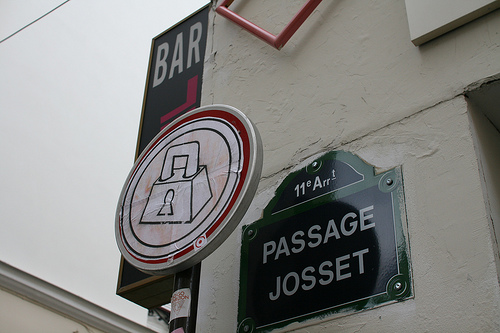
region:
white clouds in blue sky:
[47, 33, 81, 58]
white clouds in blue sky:
[75, 100, 103, 122]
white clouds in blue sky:
[19, 142, 68, 175]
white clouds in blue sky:
[4, 219, 40, 241]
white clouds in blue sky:
[5, 195, 41, 227]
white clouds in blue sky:
[16, 98, 64, 145]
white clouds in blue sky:
[39, 221, 96, 258]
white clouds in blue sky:
[58, 142, 95, 163]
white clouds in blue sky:
[49, 45, 83, 71]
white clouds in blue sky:
[7, 37, 31, 71]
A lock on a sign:
[136, 139, 213, 224]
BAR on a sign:
[149, 18, 209, 87]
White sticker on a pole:
[167, 290, 192, 319]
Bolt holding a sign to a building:
[393, 280, 400, 289]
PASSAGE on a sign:
[257, 201, 387, 265]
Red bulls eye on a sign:
[192, 233, 211, 248]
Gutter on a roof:
[0, 258, 171, 331]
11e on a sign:
[289, 180, 314, 196]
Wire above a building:
[0, 0, 81, 51]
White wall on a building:
[194, 3, 494, 331]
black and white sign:
[267, 143, 412, 298]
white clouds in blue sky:
[35, 21, 109, 79]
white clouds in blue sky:
[48, 18, 89, 55]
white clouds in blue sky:
[35, 83, 76, 128]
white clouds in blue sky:
[25, 146, 59, 188]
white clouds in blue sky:
[18, 205, 55, 250]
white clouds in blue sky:
[62, 156, 90, 183]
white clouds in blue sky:
[7, 99, 45, 134]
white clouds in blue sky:
[47, 59, 109, 104]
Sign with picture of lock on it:
[115, 100, 265, 275]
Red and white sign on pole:
[105, 100, 262, 270]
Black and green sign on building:
[235, 150, 427, 330]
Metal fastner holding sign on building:
[391, 280, 401, 290]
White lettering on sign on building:
[255, 202, 375, 297]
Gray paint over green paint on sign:
[268, 300, 410, 332]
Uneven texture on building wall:
[226, 34, 451, 166]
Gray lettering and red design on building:
[149, 18, 209, 130]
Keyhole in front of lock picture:
[155, 189, 179, 217]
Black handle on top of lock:
[158, 141, 201, 179]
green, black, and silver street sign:
[231, 143, 415, 326]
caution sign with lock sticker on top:
[115, 98, 262, 332]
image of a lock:
[134, 135, 216, 228]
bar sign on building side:
[113, 0, 209, 316]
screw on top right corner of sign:
[382, 176, 395, 187]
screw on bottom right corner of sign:
[393, 280, 400, 287]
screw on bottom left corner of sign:
[238, 320, 249, 330]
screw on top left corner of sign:
[245, 226, 252, 233]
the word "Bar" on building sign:
[147, 20, 204, 90]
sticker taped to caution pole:
[166, 284, 191, 324]